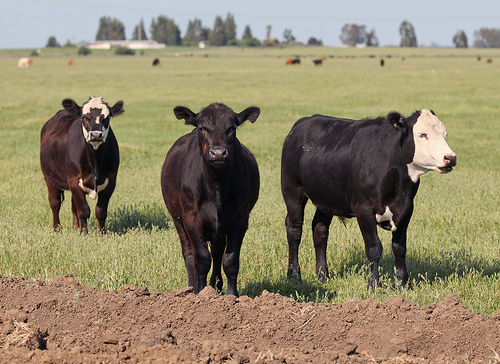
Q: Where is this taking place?
A: Outdoors.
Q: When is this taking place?
A: Daytime.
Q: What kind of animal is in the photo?
A: Cows.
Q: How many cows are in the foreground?
A: Three.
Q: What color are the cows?
A: Brown, black and white.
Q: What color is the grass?
A: Green.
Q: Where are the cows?
A: Field.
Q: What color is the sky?
A: Blue.